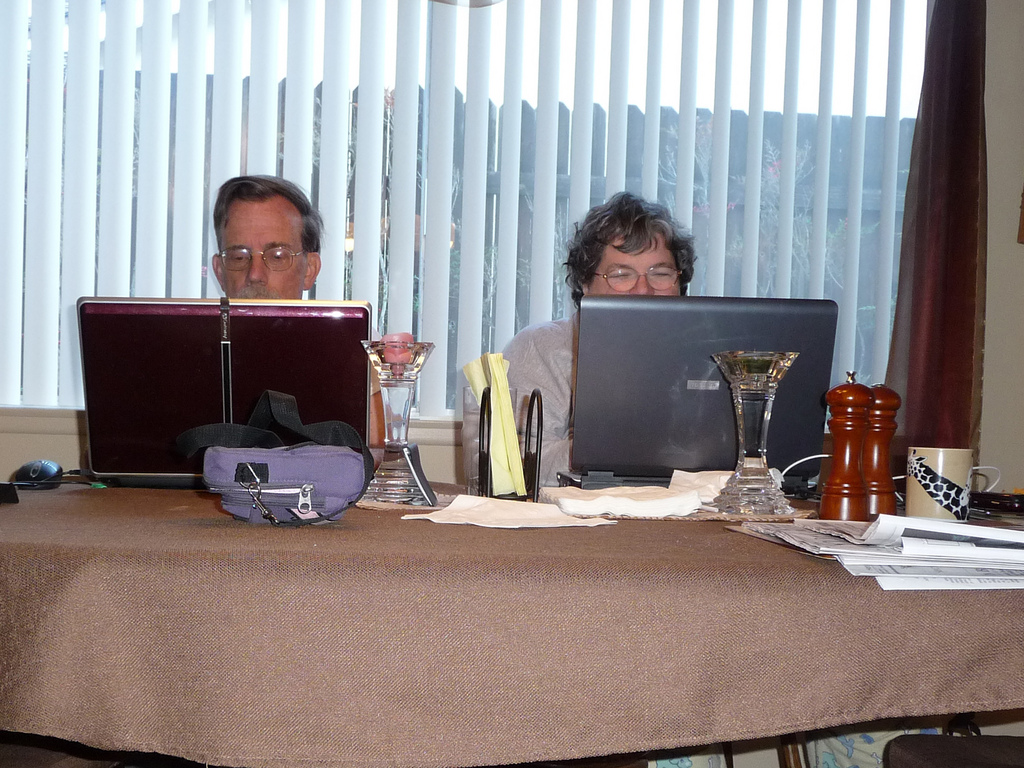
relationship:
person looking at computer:
[156, 137, 334, 310] [53, 240, 391, 513]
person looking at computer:
[560, 158, 740, 334] [558, 277, 881, 511]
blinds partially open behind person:
[0, 0, 940, 433] [502, 192, 700, 484]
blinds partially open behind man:
[0, 0, 940, 433] [213, 172, 385, 471]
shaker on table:
[821, 368, 873, 529] [0, 476, 1024, 764]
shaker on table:
[863, 381, 902, 516] [0, 476, 1024, 764]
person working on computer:
[502, 192, 700, 484] [554, 293, 836, 492]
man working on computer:
[213, 172, 385, 471] [78, 291, 379, 490]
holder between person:
[469, 350, 554, 514] [502, 192, 700, 484]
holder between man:
[469, 350, 554, 514] [213, 172, 385, 471]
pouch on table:
[201, 438, 370, 532] [0, 476, 1024, 764]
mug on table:
[901, 440, 1005, 533] [0, 476, 1024, 764]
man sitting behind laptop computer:
[213, 172, 385, 471] [74, 293, 371, 501]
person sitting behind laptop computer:
[502, 192, 700, 484] [552, 291, 838, 492]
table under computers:
[0, 483, 1023, 768] [6, 283, 1002, 714]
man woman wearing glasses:
[210, 156, 696, 490] [192, 240, 695, 276]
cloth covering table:
[6, 604, 1008, 735] [6, 519, 1008, 735]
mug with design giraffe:
[903, 446, 1000, 524] [902, 459, 978, 508]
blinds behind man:
[0, 0, 937, 437] [213, 172, 385, 471]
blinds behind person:
[0, 0, 937, 437] [447, 184, 728, 478]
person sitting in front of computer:
[572, 199, 699, 302] [557, 296, 837, 500]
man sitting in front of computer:
[212, 171, 326, 298] [78, 295, 374, 489]